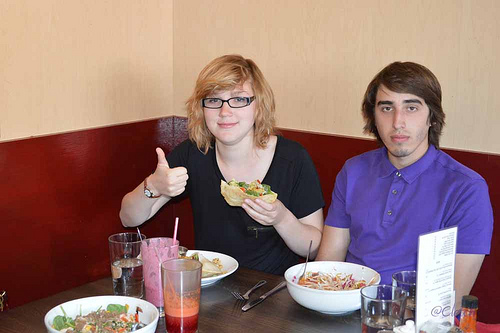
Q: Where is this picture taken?
A: Restaurant.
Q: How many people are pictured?
A: Two.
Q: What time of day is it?
A: Dayitme.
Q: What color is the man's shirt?
A: Purple.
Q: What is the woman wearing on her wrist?
A: Watch.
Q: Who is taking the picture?
A: Family.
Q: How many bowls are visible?
A: Three.